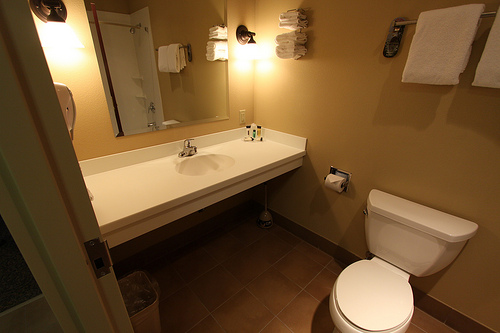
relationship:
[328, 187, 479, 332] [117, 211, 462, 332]
toilet on top of tile floor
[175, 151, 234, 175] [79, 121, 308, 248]
sink inside of counter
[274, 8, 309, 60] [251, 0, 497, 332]
towels folded on wall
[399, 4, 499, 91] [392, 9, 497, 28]
towels hanging from rack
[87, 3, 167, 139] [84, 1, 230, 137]
shower reflected in mirror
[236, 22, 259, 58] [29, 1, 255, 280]
light hanging on wall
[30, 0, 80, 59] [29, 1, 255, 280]
light hanging on wall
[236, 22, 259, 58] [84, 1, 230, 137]
light next to mirror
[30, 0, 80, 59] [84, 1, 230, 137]
light next to mirror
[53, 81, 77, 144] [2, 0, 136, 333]
soap dispenser hanging on wall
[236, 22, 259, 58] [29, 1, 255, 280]
light mounted on wall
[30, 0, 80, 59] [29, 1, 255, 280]
light mounted on wall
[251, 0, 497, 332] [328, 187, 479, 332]
wall behind toilet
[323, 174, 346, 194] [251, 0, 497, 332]
toilet paper hanging on wall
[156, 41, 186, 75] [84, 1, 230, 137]
towels reflecting in mirror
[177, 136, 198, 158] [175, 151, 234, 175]
faucet above sink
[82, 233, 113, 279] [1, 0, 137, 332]
door latch on side of door frame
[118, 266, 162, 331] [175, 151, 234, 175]
trashcan underneath sink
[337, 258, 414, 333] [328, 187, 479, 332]
lid on top of toilet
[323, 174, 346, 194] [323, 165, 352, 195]
toilet paper hanging on holder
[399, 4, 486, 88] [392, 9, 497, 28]
towels hanging off rack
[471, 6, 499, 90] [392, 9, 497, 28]
towel hanging off rack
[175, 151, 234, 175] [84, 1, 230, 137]
sink beneath mirror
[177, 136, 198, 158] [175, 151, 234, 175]
faucet behind sink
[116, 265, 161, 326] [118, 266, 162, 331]
liner inside of trashcan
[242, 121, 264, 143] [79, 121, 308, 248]
toiletries on top of counter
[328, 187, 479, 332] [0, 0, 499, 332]
toilet inside of bathroom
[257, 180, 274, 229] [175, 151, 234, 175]
toilet brush underneath sink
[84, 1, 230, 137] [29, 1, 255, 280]
mirror hanging on wall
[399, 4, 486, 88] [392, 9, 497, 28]
towels hanging from rack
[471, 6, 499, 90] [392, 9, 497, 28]
towel hanging from rack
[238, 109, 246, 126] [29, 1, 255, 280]
light switch mounted on wall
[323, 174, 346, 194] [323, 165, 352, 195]
toilet paper hung on holder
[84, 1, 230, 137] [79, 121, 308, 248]
mirror above counter